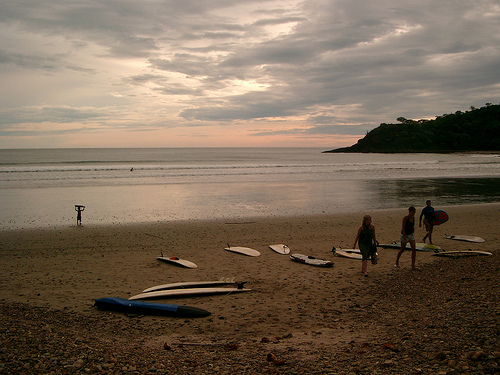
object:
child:
[75, 207, 85, 226]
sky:
[1, 0, 500, 147]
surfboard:
[431, 250, 493, 258]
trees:
[321, 102, 498, 154]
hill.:
[320, 103, 498, 156]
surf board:
[74, 204, 86, 207]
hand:
[419, 223, 423, 228]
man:
[352, 214, 377, 276]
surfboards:
[442, 232, 488, 245]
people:
[394, 206, 416, 271]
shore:
[0, 167, 499, 235]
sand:
[0, 204, 499, 374]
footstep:
[318, 283, 330, 293]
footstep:
[335, 273, 343, 282]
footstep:
[300, 285, 310, 295]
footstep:
[303, 297, 314, 307]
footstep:
[284, 306, 294, 313]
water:
[5, 150, 496, 231]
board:
[371, 242, 443, 254]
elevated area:
[322, 104, 500, 154]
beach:
[0, 162, 498, 372]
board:
[156, 254, 198, 268]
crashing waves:
[0, 151, 500, 189]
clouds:
[0, 0, 499, 143]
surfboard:
[423, 210, 449, 226]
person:
[130, 167, 134, 171]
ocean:
[0, 146, 500, 223]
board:
[223, 246, 262, 257]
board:
[268, 243, 291, 255]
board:
[289, 253, 334, 266]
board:
[330, 246, 379, 260]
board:
[74, 204, 85, 208]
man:
[419, 200, 435, 245]